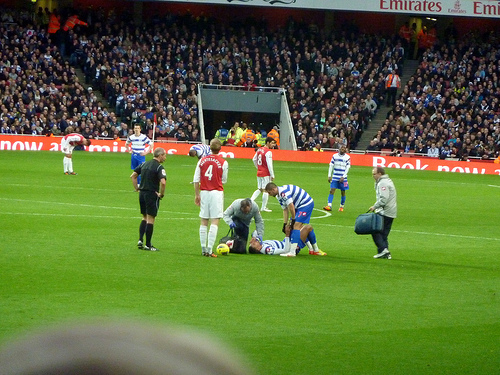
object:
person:
[47, 9, 88, 47]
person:
[62, 14, 89, 46]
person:
[427, 143, 440, 157]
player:
[130, 146, 167, 251]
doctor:
[223, 198, 265, 254]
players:
[61, 123, 398, 260]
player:
[249, 224, 327, 255]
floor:
[227, 272, 288, 319]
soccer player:
[193, 139, 229, 257]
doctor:
[354, 167, 397, 260]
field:
[0, 150, 500, 373]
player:
[125, 123, 154, 190]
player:
[324, 146, 351, 211]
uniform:
[126, 133, 154, 169]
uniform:
[329, 153, 351, 189]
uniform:
[275, 184, 314, 224]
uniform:
[260, 237, 307, 255]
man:
[385, 70, 401, 107]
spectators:
[0, 7, 500, 160]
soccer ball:
[216, 243, 230, 255]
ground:
[0, 148, 499, 371]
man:
[369, 167, 397, 260]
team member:
[250, 137, 275, 212]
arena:
[0, 0, 499, 374]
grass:
[0, 150, 500, 375]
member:
[193, 138, 229, 257]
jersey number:
[193, 154, 229, 191]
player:
[60, 132, 92, 174]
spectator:
[187, 62, 195, 70]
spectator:
[272, 62, 283, 84]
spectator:
[179, 78, 188, 95]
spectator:
[364, 95, 377, 115]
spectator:
[72, 107, 77, 115]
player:
[265, 182, 314, 257]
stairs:
[350, 60, 421, 150]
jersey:
[193, 155, 229, 191]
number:
[204, 165, 213, 181]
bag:
[354, 210, 385, 235]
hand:
[369, 206, 376, 212]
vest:
[387, 74, 400, 88]